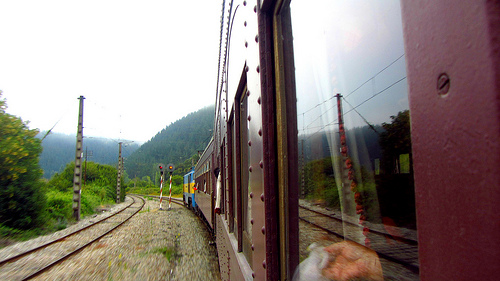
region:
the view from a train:
[102, 50, 419, 242]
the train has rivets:
[201, 60, 358, 234]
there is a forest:
[41, 78, 451, 270]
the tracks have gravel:
[42, 60, 243, 236]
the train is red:
[163, 132, 442, 267]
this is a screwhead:
[421, 39, 473, 119]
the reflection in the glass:
[213, 25, 464, 260]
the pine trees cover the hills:
[37, 70, 149, 218]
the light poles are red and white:
[125, 155, 205, 240]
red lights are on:
[135, 142, 180, 189]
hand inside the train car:
[309, 226, 394, 275]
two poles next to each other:
[151, 160, 175, 217]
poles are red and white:
[154, 171, 176, 205]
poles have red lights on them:
[148, 161, 183, 172]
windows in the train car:
[205, 130, 426, 246]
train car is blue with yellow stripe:
[178, 168, 201, 204]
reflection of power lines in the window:
[297, 82, 444, 207]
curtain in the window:
[332, 108, 392, 238]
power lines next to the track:
[63, 90, 135, 215]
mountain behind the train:
[143, 112, 214, 173]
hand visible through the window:
[307, 225, 384, 280]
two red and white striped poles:
[153, 170, 179, 209]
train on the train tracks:
[165, 0, 481, 275]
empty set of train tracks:
[4, 169, 156, 274]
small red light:
[165, 159, 177, 176]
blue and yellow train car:
[175, 164, 199, 210]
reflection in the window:
[321, 94, 376, 206]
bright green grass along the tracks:
[37, 177, 108, 218]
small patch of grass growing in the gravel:
[146, 236, 182, 265]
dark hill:
[126, 100, 210, 180]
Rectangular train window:
[270, 0, 441, 279]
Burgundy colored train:
[196, 32, 268, 274]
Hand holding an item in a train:
[287, 203, 448, 278]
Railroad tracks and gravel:
[0, 202, 164, 278]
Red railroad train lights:
[143, 154, 188, 236]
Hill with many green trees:
[118, 97, 211, 222]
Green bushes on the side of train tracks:
[9, 143, 117, 235]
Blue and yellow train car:
[173, 165, 205, 215]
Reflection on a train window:
[278, 88, 413, 268]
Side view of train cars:
[138, 85, 394, 278]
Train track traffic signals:
[146, 151, 186, 220]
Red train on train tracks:
[176, 4, 472, 264]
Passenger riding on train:
[297, 171, 415, 278]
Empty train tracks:
[0, 185, 153, 276]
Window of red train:
[265, 0, 445, 280]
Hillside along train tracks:
[121, 85, 221, 190]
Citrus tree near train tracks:
[1, 90, 71, 231]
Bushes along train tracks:
[42, 158, 124, 229]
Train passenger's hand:
[268, 229, 398, 277]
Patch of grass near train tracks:
[135, 234, 192, 269]